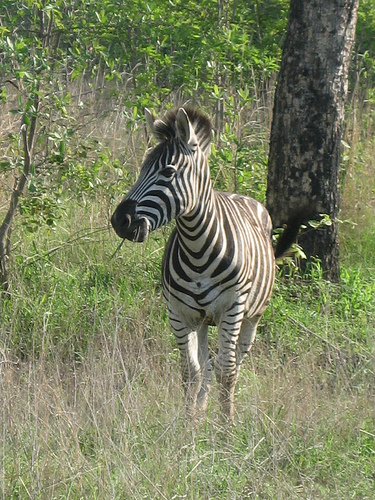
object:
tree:
[0, 34, 64, 273]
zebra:
[111, 86, 328, 428]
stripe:
[146, 189, 175, 220]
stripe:
[155, 178, 181, 215]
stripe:
[223, 338, 239, 346]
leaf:
[56, 104, 68, 117]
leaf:
[56, 139, 67, 154]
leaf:
[237, 58, 252, 76]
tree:
[265, 0, 360, 279]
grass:
[1, 267, 79, 500]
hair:
[152, 98, 178, 146]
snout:
[110, 200, 134, 238]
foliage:
[78, 0, 139, 79]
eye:
[159, 164, 178, 179]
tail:
[275, 196, 316, 259]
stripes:
[214, 189, 276, 312]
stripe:
[167, 314, 183, 330]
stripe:
[174, 338, 194, 347]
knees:
[178, 364, 205, 388]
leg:
[168, 312, 204, 422]